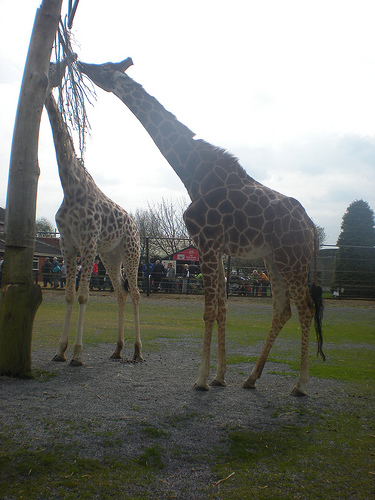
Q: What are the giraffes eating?
A: Leaves.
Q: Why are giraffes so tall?
A: To reach their food.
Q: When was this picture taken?
A: During the day.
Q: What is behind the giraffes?
A: A fence.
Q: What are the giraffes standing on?
A: Grass.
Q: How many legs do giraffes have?
A: Four.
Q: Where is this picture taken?
A: A zoo.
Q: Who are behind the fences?
A: People.